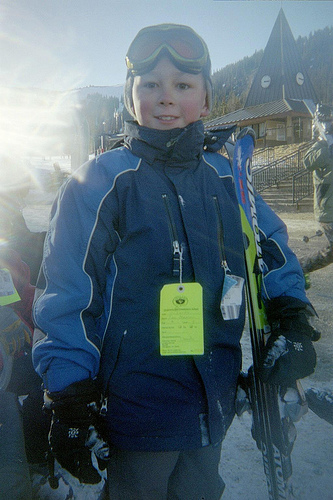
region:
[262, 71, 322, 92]
clocks on the building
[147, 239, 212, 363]
yellow tag on the jacket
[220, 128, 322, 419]
boy holding skis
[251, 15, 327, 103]
roof comes to a peak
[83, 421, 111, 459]
snow on the glove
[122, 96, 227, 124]
boy's cheeks are red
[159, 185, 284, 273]
two small zippers on the jacket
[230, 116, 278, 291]
skis are blue and green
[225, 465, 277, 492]
snow on the ground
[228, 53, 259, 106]
trees on the mountains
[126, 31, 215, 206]
A young boy wearing ski goggles.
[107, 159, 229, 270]
A light and dark blue coat with white stripes.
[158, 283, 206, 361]
A neon yellow ski lift tag.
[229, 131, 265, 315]
A set of skis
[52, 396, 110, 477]
A black ski glove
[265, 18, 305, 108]
A ski chalet with clocks.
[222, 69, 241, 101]
Trees in the distance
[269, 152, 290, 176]
A black guard rail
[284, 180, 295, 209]
A set of stairs.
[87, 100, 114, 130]
Trees in the distance.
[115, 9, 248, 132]
a goggle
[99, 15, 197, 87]
a goggle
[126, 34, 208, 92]
a goggle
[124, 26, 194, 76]
boy wears green goggles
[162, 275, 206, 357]
tag is neon yellow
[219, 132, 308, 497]
boy holds skis in left hand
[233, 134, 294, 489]
skis are blue and green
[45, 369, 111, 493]
winter gloves are black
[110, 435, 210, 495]
boy wears blue jeans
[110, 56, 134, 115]
boy wears grey hat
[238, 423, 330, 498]
snow is behind boy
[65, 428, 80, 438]
white logo on black gloves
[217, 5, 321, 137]
ski lodge in background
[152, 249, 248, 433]
A yellow tag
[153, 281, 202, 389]
A yellow tag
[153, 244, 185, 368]
A yellow tag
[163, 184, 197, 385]
A yellow tag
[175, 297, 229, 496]
A yellow tag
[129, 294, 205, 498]
A yellow tag